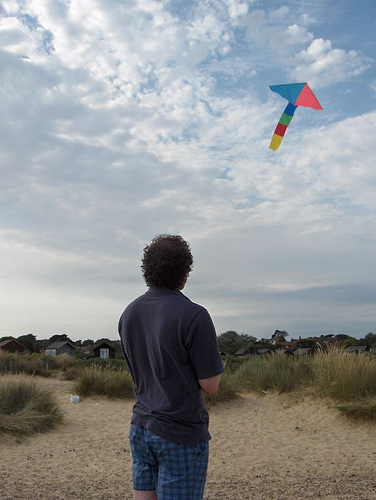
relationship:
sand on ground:
[207, 401, 347, 486] [44, 399, 328, 483]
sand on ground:
[0, 401, 376, 500] [44, 399, 328, 483]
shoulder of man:
[177, 296, 209, 327] [118, 233, 222, 500]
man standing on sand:
[117, 231, 223, 497] [0, 373, 375, 498]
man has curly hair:
[118, 233, 222, 500] [142, 232, 194, 290]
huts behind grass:
[36, 337, 366, 355] [1, 345, 375, 437]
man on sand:
[117, 231, 223, 497] [5, 396, 371, 498]